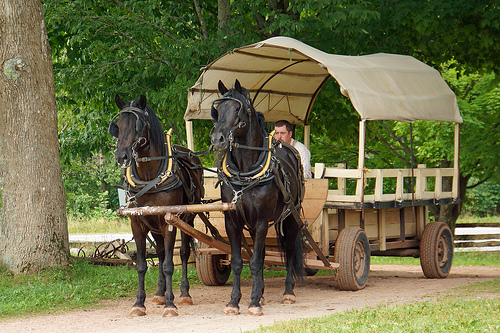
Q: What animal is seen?
A: Horse.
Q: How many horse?
A: 2.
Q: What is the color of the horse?
A: Black.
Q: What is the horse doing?
A: Pulling the cart.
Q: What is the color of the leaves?
A: Green.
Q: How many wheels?
A: 4.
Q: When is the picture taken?
A: Daytime.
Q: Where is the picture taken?
A: On a trail.